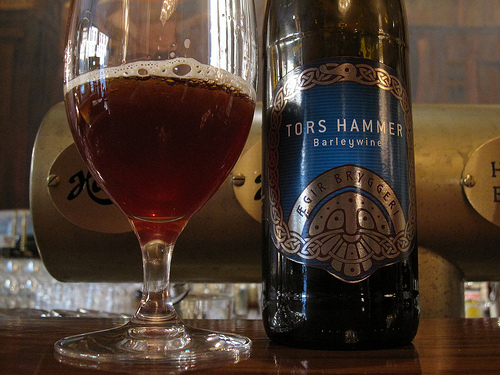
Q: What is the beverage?
A: Beer wine.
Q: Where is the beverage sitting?
A: On the bar.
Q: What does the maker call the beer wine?
A: Barleywine.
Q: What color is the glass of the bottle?
A: Green.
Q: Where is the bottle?
A: Next to the glass of beer wine.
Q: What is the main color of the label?
A: Blue.